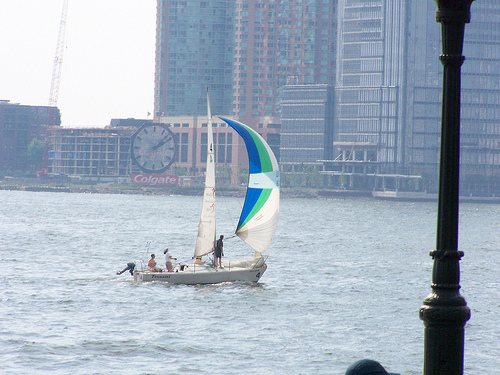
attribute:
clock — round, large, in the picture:
[127, 124, 179, 174]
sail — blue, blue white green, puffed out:
[217, 112, 280, 252]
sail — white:
[195, 96, 216, 258]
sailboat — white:
[122, 99, 279, 287]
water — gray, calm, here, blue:
[0, 187, 500, 372]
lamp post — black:
[418, 2, 471, 375]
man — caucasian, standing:
[208, 232, 226, 268]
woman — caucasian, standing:
[162, 243, 177, 270]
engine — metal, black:
[115, 260, 136, 275]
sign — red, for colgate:
[131, 173, 175, 185]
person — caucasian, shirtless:
[147, 252, 160, 272]